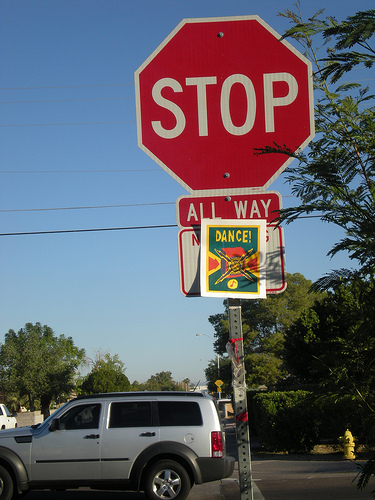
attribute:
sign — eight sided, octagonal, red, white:
[133, 10, 317, 192]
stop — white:
[150, 71, 299, 139]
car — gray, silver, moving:
[1, 387, 237, 499]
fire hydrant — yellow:
[336, 427, 358, 463]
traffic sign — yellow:
[213, 377, 225, 390]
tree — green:
[252, 3, 373, 491]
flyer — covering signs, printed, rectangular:
[199, 216, 269, 302]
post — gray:
[226, 299, 255, 499]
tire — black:
[139, 456, 193, 499]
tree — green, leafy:
[0, 319, 88, 429]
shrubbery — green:
[252, 386, 317, 454]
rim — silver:
[151, 469, 182, 498]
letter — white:
[145, 75, 188, 141]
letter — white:
[183, 71, 220, 141]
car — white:
[0, 400, 19, 430]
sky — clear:
[0, 1, 373, 393]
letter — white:
[216, 71, 260, 140]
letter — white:
[260, 70, 302, 136]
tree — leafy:
[76, 368, 131, 400]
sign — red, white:
[176, 193, 288, 231]